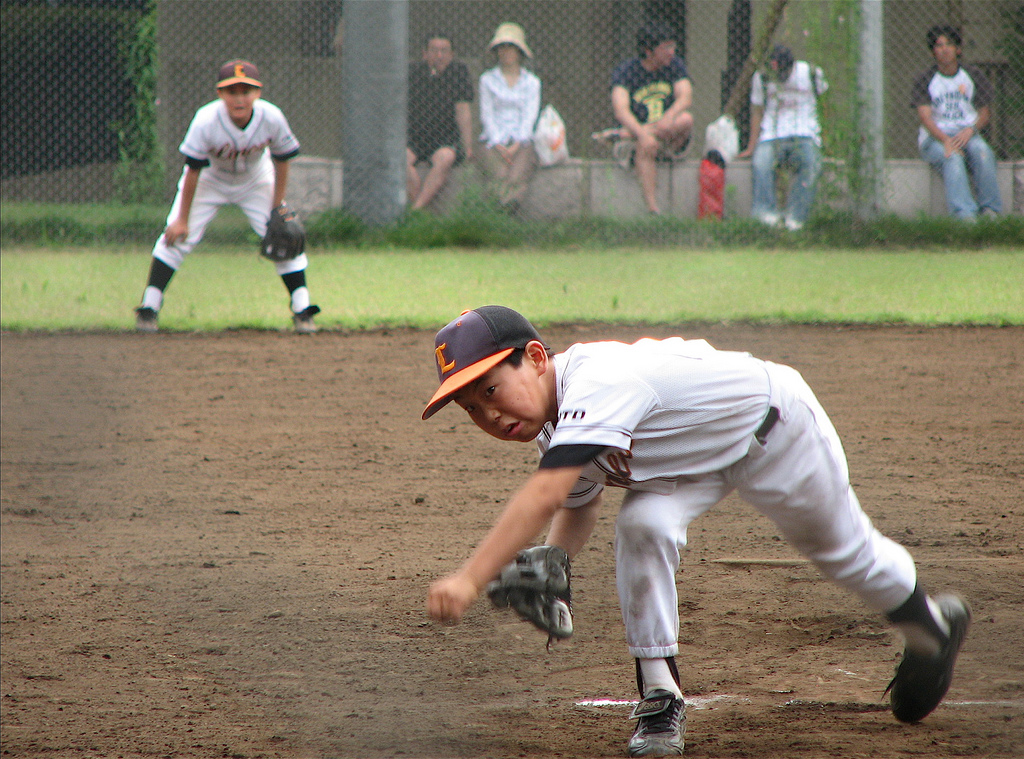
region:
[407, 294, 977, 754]
young boy pitching baseball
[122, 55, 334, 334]
young boy standing in baseball field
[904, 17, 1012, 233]
man in jeans sitting on short wall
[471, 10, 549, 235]
woman in white shirt watching baseball game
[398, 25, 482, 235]
man in black shirt sitting with ankles crossed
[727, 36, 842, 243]
person in white shirt sitting on wall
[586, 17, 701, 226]
man in shorts with head turned to side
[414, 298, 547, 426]
black and yellow baseball hat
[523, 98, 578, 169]
white bag sitting next to woman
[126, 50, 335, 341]
young baseball player leaning forward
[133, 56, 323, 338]
A boy with a black and orange hat playing baseball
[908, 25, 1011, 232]
A man with a white shirt and blue jeans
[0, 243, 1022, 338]
Green grass on a baseball field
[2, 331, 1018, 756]
Brown dirt baseball field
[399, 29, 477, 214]
Man in a black shirt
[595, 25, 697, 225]
A man sitting on a concrete ledge in shorts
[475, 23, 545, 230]
Woman in a white shirt with a hat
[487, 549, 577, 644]
Black baseball glove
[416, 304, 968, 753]
the boy is wearing a glove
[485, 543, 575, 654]
the baseball glove is black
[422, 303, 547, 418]
the hat is black and orange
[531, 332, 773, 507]
the jersey is white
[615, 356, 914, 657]
the pants are white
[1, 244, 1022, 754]
the green grass and the brown dirt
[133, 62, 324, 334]
the boy is bending over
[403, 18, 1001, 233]
the people are sitting down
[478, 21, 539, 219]
the woman is wearing a hat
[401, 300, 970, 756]
child in pitching stance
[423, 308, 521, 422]
orange and black hat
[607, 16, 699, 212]
man wearing black shirt with yellow logo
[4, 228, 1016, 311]
grass on the field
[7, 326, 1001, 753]
dirt on the field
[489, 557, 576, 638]
black baseball glove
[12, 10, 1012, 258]
chain link fence behind the field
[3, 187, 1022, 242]
weeds growing along the fence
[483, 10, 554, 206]
woman wearing hat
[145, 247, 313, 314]
black and white socks